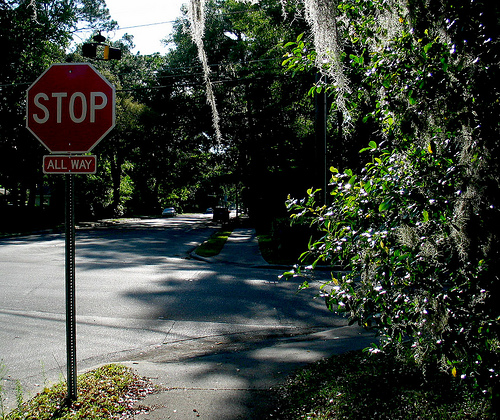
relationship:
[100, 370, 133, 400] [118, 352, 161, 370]
grass near curb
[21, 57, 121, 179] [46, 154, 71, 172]
sign has white lettering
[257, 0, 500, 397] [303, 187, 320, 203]
tree has green leaves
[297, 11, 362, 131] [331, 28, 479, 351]
moss hanging off of a tree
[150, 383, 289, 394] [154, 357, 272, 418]
seam in a sidewalk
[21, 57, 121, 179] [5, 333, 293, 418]
sign on corner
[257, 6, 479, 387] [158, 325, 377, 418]
tree on or side of sidewalk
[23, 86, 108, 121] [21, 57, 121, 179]
letter on sign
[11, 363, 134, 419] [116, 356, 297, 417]
grass on sidewalk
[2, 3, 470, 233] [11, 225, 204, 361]
trees covering street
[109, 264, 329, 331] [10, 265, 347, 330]
shadows on street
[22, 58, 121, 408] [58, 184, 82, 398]
sign attached pole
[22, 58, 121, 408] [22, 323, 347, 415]
sign on sidewalk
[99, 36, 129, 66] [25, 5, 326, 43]
light attached line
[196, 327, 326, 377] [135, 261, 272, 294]
area with sunlight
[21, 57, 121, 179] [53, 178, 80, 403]
sign on post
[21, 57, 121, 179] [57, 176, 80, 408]
sign on post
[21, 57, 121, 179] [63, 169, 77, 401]
sign holding pole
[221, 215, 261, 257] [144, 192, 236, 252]
sidewalk leading block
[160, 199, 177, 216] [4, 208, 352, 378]
car parked street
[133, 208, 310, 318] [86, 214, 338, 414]
street between sidewalk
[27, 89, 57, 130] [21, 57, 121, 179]
letter on sign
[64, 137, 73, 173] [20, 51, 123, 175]
screws on sign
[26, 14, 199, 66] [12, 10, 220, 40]
light hanging wire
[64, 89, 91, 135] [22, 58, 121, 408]
letter on sign